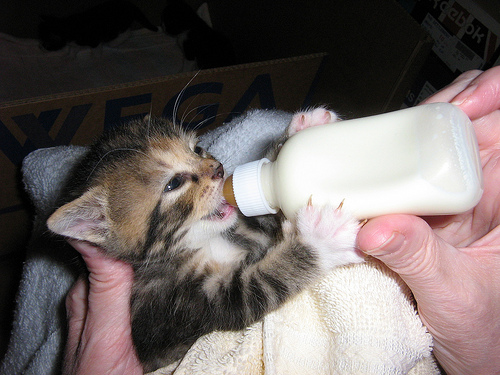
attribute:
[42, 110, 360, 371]
kitten — bottle fed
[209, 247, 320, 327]
leg — grey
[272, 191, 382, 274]
paw — white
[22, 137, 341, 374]
kitten — bottle fed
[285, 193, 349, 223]
claws — extended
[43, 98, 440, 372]
towel — white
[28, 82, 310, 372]
kitten — holding